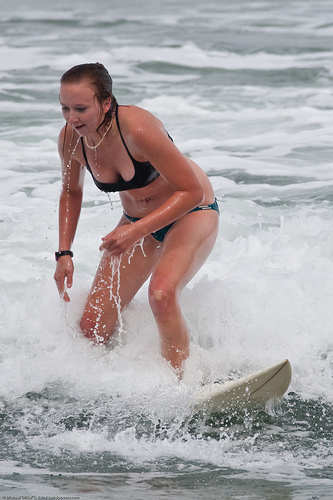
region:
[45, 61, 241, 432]
woman surfing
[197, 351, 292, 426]
white board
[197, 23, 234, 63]
white and gray waves in ocean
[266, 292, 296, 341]
white and gray waves in ocean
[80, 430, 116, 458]
white and gray waves in ocean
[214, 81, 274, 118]
white and gray waves in ocean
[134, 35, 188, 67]
white and gray waves in ocean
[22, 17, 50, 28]
white and gray waves in ocean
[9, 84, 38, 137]
white and gray waves in ocean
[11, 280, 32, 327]
white and gray waves in ocean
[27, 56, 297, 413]
a woman in a bikini surfing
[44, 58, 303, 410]
a woman surfing on a white board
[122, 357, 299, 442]
a white surf board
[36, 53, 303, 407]
a woman on a surfboard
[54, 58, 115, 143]
the head of a woman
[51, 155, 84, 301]
the arm of a woman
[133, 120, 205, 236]
the arm of a woman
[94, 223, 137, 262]
the hand of a woman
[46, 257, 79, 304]
the hand of a woman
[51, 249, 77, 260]
the black watch of a woman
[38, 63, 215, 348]
this is a woman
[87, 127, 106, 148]
the woman is wearing a neclace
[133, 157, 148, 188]
she is wearing a black bra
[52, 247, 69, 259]
she is wearing a watch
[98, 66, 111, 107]
she has black hair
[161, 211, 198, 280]
that is a thigh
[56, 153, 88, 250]
this is an arm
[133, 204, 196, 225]
this is an arm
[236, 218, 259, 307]
that is calm waters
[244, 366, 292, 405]
part of a surf board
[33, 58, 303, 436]
woman standing on white surfboard in water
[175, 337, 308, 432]
brown and white tip of surfboard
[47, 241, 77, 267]
black watch on wrist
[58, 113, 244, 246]
balck and green bikini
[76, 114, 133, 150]
white beaded necklace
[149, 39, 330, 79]
white froth on top of water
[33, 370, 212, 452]
water splash in body of water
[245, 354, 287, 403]
brown line down the center of surfboard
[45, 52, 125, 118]
brown wet hair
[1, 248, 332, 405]
white wave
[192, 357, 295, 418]
A white surf board.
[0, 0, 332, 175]
Gray ocean water.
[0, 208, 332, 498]
A small ocean wave.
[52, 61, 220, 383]
A woman surfing in the ocean.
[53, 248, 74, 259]
A water proof watch.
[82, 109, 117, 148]
A white necklace.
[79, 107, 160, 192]
A black bikini top.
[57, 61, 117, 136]
A female humans head.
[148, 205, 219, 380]
A female human leg.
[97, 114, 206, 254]
A female human arm.